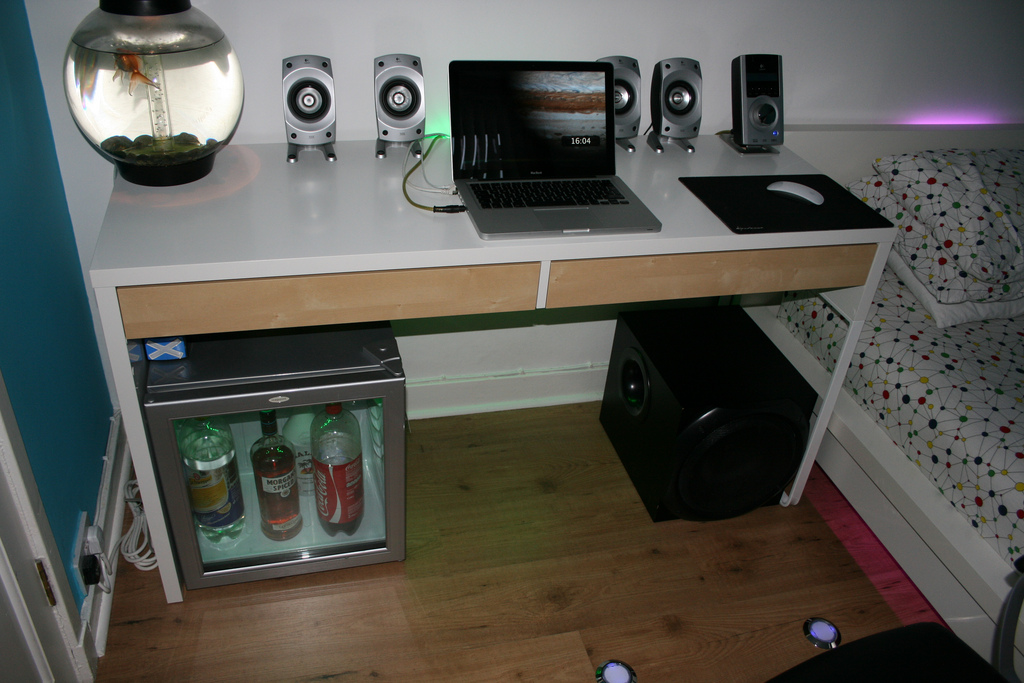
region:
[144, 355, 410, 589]
mini-fridge has rum and sodas inside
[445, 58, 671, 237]
macbook with Jupiter on the screen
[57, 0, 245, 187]
goldfish bowl with goldfish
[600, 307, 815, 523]
subwoofer underneath desk and next to bed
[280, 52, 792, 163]
computer sound system with four speakers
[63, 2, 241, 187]
goldfish swimming in bowl on desk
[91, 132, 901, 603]
white desk with brown wooden drawers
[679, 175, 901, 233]
wireless mouse on mousepad on desk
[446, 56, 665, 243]
open laptop on desk displaying Jupiter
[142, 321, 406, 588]
small beverage refrigerator under desk on floor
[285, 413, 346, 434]
bottle in the fridge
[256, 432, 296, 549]
bottle in the fridge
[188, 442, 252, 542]
bottle in the fridge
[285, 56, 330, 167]
speaker on the table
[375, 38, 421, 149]
speaker on the table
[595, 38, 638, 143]
speaker on the table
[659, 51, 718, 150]
speaker on the table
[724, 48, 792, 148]
speaker on the table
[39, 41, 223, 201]
fishbowl on the table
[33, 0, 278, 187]
Fishbowl with goldfish inside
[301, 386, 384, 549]
Coca cola behind glass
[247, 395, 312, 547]
Alcoholic beverage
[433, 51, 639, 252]
Laptop with planet as wallpaper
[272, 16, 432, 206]
Two small speakers on desk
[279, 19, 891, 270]
Desk setup containing a laptop, speakers, and mouse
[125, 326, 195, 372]
Small Scottish flag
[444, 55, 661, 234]
A laptop on the table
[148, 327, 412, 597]
A drinks chest under the table.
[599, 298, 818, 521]
The black sound system under the table.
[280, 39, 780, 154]
The small speaker systems next to the wall.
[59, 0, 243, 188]
A cylindrical fish aquarium.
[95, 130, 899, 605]
A white table in a room.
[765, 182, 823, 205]
A white cordless mouse.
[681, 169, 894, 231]
A dark mouse pad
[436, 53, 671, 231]
laptop sits on the table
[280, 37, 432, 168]
speakers sit on the table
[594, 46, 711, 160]
speakers sit on the table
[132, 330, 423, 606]
drinks are in the mini fridge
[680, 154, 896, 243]
white mouse is on the black mousepad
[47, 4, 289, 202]
a glass fishbowl sits on the white table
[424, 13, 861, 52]
the wall is white and flat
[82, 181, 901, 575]
the table is long and white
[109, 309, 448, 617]
The fridge is silver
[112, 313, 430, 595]
The fridge is on the floor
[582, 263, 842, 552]
The speaker is black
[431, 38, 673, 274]
The laptop is open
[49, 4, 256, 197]
The goldfish is in a bowl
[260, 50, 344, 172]
The speaker is on the desk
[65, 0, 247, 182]
A fish bowl on a table.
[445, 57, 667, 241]
An open laptop computer.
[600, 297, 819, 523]
A small black sub woofer.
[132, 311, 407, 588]
A small metal mini fridge.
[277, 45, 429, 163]
A speaker system on a table.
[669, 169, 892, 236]
A mouse pad on a desk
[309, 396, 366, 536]
A bottle of coke.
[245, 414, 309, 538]
A bottle of booze.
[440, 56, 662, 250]
A laptop computer.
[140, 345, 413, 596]
A small refrigerator with a glass door.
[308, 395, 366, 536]
Large container of Coca Cola.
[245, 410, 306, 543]
A bottle of liquor.